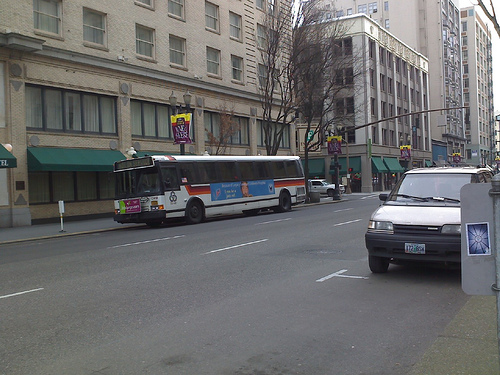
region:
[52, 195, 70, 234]
Sign on the sidewalk.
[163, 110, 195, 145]
Sign on the pole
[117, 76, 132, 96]
Circle medallion on the building.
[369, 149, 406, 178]
Green awnings on the building.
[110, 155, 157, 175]
Lighted sign on the bus.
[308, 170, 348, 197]
Vehicle on the street.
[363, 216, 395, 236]
Headlight on the car.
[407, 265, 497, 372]
Sidewalk beside the street.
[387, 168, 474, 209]
Front windshield on the car.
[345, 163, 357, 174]
Red light on signal.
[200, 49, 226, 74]
window on the building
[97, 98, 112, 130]
window on the building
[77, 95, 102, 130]
window on the building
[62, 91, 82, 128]
window on the building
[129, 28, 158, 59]
window on the building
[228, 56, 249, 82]
window on the building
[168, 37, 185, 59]
window on the building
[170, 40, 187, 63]
window on the building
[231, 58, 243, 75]
window on the building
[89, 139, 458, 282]
cars parked on street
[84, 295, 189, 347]
the road is asphalt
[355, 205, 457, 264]
front of the car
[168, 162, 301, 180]
windows on the bsu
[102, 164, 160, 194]
front of the bus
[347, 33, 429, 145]
windows on the building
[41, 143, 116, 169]
awning on the building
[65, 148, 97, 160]
the awning is green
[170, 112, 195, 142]
flag on the pole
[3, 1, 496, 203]
Bulidings along an avenue.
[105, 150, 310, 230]
Transit bus stopping aside of the street.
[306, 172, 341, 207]
White truck stopping at an intersection.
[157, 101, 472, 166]
Light poles with colorful ad.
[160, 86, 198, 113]
Pole light with two lanterns.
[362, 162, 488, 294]
A beige car parked on the street.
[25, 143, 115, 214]
Store is closed.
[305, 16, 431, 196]
Building with stores at the bottom floor.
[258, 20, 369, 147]
Leafless trees on the street.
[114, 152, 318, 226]
Long transit bus with an add on the side.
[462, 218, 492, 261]
Sticker on the sign.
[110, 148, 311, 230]
Bus on the street.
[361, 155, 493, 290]
Vehicle on the road.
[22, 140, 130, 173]
Green awning on the building.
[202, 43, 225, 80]
window in the building.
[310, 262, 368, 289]
white parking line on the road.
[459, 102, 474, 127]
Traffic signal on the pole.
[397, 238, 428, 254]
License plate on the car.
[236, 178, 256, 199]
Person on the sign.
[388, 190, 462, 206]
black wipers on the car.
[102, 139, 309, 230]
a long white bus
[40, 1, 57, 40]
a window on the building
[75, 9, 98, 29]
a window on the building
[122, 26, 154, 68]
a window on the building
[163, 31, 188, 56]
a window on the building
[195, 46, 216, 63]
a window on the building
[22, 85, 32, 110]
a window on the building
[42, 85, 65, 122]
a window on the building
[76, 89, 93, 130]
a window on the building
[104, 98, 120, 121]
a window on the building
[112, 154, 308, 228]
A mostly white bus.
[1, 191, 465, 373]
A paved grey road.